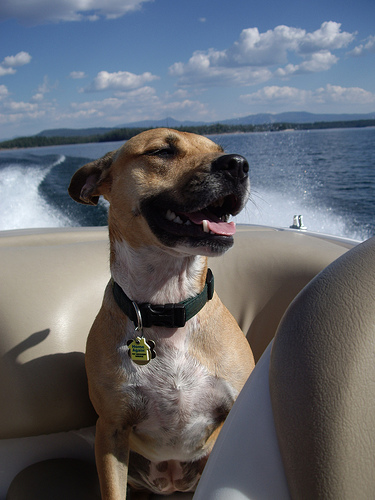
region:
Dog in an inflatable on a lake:
[43, 71, 368, 456]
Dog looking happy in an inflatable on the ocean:
[10, 103, 358, 273]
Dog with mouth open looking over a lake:
[60, 111, 360, 252]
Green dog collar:
[54, 265, 224, 327]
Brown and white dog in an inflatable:
[2, 105, 323, 356]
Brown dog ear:
[51, 130, 119, 209]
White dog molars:
[150, 206, 192, 241]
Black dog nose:
[204, 144, 264, 183]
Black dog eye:
[132, 120, 193, 170]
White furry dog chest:
[73, 299, 274, 452]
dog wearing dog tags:
[121, 325, 172, 372]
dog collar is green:
[91, 254, 230, 326]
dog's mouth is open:
[117, 182, 280, 253]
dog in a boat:
[12, 101, 228, 409]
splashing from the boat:
[234, 123, 350, 231]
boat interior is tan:
[308, 297, 371, 432]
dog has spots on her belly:
[150, 451, 209, 498]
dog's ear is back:
[65, 131, 138, 208]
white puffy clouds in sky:
[204, 19, 365, 92]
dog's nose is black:
[206, 146, 287, 209]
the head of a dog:
[61, 120, 269, 265]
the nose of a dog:
[205, 146, 250, 183]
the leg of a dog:
[90, 416, 135, 494]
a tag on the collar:
[123, 332, 154, 363]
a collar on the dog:
[102, 262, 215, 328]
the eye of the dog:
[139, 136, 176, 160]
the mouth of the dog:
[146, 183, 247, 243]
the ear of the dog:
[60, 144, 121, 211]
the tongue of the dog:
[182, 209, 238, 237]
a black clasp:
[135, 297, 192, 332]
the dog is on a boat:
[87, 117, 253, 421]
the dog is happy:
[62, 136, 285, 294]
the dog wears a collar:
[100, 257, 225, 328]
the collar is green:
[144, 268, 209, 330]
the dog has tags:
[121, 316, 164, 369]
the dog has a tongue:
[210, 219, 229, 235]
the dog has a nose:
[203, 147, 252, 183]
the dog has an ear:
[54, 145, 112, 217]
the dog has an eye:
[140, 141, 186, 164]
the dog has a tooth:
[187, 216, 214, 231]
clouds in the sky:
[201, 16, 316, 94]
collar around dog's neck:
[111, 327, 158, 384]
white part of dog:
[144, 357, 207, 423]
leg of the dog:
[82, 437, 142, 497]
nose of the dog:
[214, 150, 259, 195]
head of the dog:
[85, 100, 270, 265]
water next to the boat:
[297, 150, 341, 189]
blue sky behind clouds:
[142, 10, 182, 37]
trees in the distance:
[284, 103, 329, 138]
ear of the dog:
[68, 143, 109, 212]